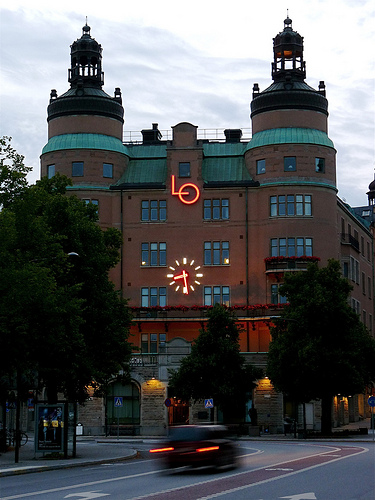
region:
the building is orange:
[33, 48, 356, 418]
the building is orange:
[36, 66, 329, 425]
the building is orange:
[36, 38, 356, 461]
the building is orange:
[31, 68, 333, 459]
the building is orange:
[30, 68, 348, 417]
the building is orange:
[38, 61, 368, 413]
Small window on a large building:
[131, 194, 151, 225]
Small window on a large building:
[147, 198, 159, 223]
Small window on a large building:
[158, 197, 169, 223]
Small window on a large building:
[202, 193, 213, 223]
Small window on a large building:
[220, 194, 234, 227]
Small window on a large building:
[251, 154, 268, 178]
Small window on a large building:
[279, 151, 298, 183]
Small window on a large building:
[308, 150, 330, 176]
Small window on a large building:
[176, 157, 191, 183]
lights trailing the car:
[141, 444, 221, 454]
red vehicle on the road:
[157, 414, 245, 461]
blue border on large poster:
[27, 401, 68, 448]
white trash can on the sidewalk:
[71, 419, 85, 434]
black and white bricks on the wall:
[141, 388, 159, 407]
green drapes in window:
[103, 383, 149, 424]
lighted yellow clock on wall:
[161, 252, 212, 299]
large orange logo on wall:
[164, 172, 207, 214]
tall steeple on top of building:
[67, 15, 108, 88]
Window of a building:
[133, 281, 174, 308]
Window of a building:
[196, 279, 239, 311]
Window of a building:
[267, 277, 301, 309]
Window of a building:
[266, 234, 338, 261]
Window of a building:
[199, 229, 236, 268]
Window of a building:
[136, 238, 172, 270]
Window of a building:
[136, 196, 171, 224]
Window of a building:
[200, 195, 228, 222]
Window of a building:
[267, 191, 314, 219]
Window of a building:
[138, 327, 170, 357]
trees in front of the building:
[143, 229, 354, 458]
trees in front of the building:
[141, 208, 356, 471]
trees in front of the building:
[133, 205, 334, 466]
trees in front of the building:
[166, 249, 325, 434]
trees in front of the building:
[173, 248, 335, 439]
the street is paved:
[115, 399, 326, 497]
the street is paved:
[139, 411, 315, 488]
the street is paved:
[145, 408, 367, 498]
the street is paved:
[175, 409, 321, 475]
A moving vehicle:
[133, 411, 247, 475]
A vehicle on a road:
[127, 414, 357, 485]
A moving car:
[132, 412, 266, 479]